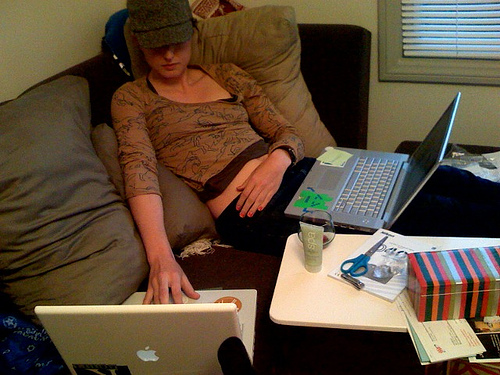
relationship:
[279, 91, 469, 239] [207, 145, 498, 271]
laptop on girl's lap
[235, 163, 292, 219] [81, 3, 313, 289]
hand on girl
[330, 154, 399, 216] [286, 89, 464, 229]
keyboard on laptop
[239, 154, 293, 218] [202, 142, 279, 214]
hand on stomach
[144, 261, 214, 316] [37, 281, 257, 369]
hand on computer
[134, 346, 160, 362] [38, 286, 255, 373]
logo on computer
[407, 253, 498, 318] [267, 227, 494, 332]
striped box on table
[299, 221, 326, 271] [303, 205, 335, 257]
bottle next to glass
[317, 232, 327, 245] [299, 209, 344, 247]
liquid in glass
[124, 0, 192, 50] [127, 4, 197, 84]
cap on head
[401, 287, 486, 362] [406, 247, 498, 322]
papers under box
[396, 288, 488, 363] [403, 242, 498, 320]
documents under box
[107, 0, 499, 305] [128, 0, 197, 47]
girl wearing cap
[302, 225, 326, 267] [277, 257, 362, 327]
lotion on table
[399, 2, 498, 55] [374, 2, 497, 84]
blinds covering window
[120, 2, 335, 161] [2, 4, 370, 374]
pillow on sofa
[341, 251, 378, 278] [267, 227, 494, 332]
scissors on table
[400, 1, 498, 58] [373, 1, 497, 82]
window has frame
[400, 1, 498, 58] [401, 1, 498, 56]
window has venetian blind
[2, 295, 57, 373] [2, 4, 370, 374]
cloth on sofa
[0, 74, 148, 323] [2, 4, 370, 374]
pillow on sofa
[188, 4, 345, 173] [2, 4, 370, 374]
pillow on sofa